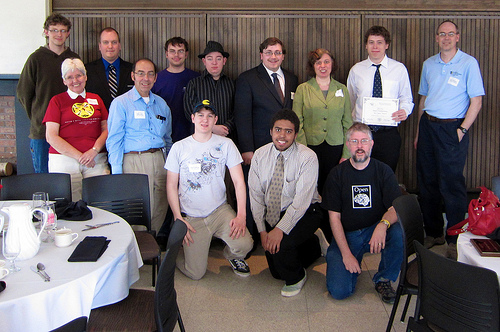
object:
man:
[15, 13, 81, 174]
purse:
[447, 185, 500, 235]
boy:
[347, 25, 415, 173]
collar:
[67, 87, 87, 99]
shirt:
[42, 88, 109, 155]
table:
[0, 200, 144, 332]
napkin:
[67, 235, 111, 262]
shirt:
[106, 85, 174, 175]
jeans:
[326, 222, 405, 300]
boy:
[183, 40, 237, 212]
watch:
[458, 126, 468, 135]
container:
[1, 204, 49, 261]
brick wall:
[0, 96, 18, 166]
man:
[84, 27, 133, 114]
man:
[316, 121, 406, 304]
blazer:
[291, 76, 353, 158]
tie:
[265, 153, 284, 227]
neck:
[273, 141, 294, 156]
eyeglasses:
[135, 72, 155, 77]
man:
[248, 108, 330, 296]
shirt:
[247, 141, 322, 235]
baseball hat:
[193, 99, 217, 114]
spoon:
[37, 262, 51, 281]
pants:
[123, 148, 169, 236]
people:
[292, 48, 354, 197]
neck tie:
[371, 64, 382, 98]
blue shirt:
[102, 56, 121, 86]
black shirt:
[84, 56, 134, 114]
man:
[413, 19, 485, 260]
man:
[105, 58, 173, 237]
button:
[153, 138, 156, 140]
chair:
[405, 240, 500, 332]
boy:
[164, 100, 255, 281]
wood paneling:
[135, 9, 380, 37]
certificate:
[362, 97, 399, 127]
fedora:
[197, 40, 229, 59]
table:
[452, 214, 499, 274]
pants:
[175, 202, 254, 281]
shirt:
[184, 68, 235, 136]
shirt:
[418, 47, 486, 119]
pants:
[415, 110, 470, 245]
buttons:
[323, 106, 328, 132]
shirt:
[323, 157, 403, 232]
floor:
[169, 254, 418, 332]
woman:
[41, 57, 109, 202]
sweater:
[16, 43, 82, 139]